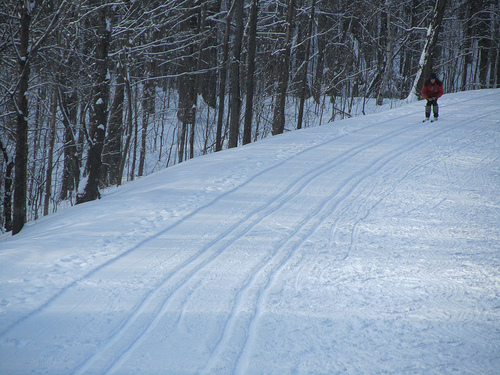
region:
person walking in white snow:
[400, 55, 447, 122]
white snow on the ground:
[201, 199, 249, 230]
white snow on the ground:
[324, 198, 384, 252]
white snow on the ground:
[277, 281, 335, 318]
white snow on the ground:
[371, 269, 405, 301]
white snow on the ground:
[155, 252, 212, 279]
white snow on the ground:
[54, 292, 129, 332]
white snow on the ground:
[191, 231, 262, 292]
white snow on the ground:
[348, 155, 403, 200]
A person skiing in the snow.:
[419, 68, 446, 122]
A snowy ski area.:
[0, 84, 499, 374]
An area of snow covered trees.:
[0, 0, 499, 238]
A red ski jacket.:
[420, 79, 446, 104]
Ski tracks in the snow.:
[0, 105, 499, 373]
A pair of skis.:
[419, 115, 442, 123]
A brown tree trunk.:
[8, 6, 33, 236]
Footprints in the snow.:
[0, 93, 426, 327]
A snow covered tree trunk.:
[407, 0, 449, 103]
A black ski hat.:
[428, 73, 438, 83]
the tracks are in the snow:
[95, 221, 283, 354]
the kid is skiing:
[409, 62, 455, 129]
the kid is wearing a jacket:
[417, 77, 446, 102]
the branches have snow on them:
[133, 34, 216, 86]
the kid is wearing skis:
[415, 64, 448, 120]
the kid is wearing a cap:
[424, 72, 440, 80]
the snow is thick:
[177, 211, 291, 304]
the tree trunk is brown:
[225, 80, 244, 127]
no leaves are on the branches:
[133, 64, 220, 79]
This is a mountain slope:
[12, 3, 496, 373]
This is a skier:
[419, 55, 440, 133]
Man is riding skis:
[419, 68, 442, 135]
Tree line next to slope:
[9, 0, 484, 232]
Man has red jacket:
[407, 69, 444, 98]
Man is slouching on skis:
[422, 75, 445, 120]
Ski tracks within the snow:
[14, 101, 480, 353]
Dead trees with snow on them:
[0, 0, 497, 151]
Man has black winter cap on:
[422, 74, 438, 86]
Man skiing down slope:
[410, 78, 449, 123]